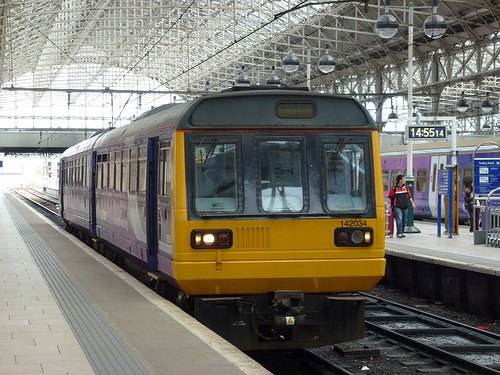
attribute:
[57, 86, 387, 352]
train — commuter, yellow, grey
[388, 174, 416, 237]
person — standing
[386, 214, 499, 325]
platform — cement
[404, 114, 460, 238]
clock — digital, military time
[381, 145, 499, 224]
train — purple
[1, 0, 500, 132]
rails — metal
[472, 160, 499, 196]
sign — blue, white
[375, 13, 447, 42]
lights — hanging, overhead lights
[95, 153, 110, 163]
windows — open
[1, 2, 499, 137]
ceiling — metal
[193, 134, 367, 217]
windows — windshields